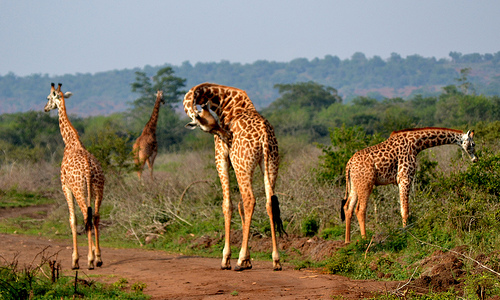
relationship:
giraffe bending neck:
[180, 81, 284, 272] [184, 82, 226, 107]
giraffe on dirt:
[44, 80, 105, 270] [6, 230, 394, 293]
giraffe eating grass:
[343, 126, 478, 241] [428, 159, 484, 215]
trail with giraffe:
[6, 196, 387, 298] [44, 80, 105, 270]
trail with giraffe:
[6, 196, 387, 298] [180, 81, 284, 272]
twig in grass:
[45, 255, 66, 282] [5, 260, 143, 298]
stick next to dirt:
[411, 231, 484, 275] [399, 241, 484, 291]